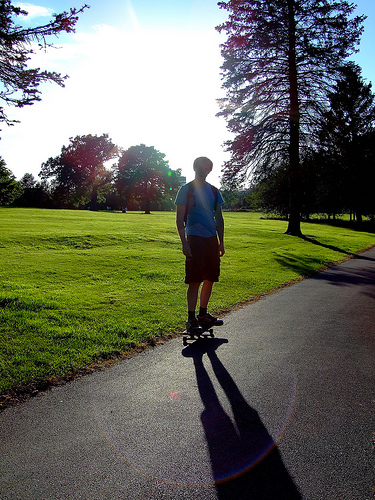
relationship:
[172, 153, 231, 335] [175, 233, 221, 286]
man wearing shorts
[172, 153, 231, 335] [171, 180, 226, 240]
man wearing shirt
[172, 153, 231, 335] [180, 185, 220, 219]
man wearing backpack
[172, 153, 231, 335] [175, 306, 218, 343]
man standing on skateboard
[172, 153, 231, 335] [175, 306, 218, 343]
man riding on skateboard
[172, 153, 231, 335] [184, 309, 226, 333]
man has shoes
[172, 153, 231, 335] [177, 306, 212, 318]
man has socks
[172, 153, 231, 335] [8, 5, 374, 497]
man i park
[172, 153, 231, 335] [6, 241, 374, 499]
man on path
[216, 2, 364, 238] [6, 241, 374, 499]
tree beside path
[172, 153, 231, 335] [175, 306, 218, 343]
man riding skateboard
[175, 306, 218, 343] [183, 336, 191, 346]
skateboard has wheel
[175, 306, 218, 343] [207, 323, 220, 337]
skateboard has wheel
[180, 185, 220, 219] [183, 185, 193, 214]
backpack has straps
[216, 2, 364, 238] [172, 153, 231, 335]
tree behind man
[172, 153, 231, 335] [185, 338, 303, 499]
man has shadow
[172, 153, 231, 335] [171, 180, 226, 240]
man has shirt